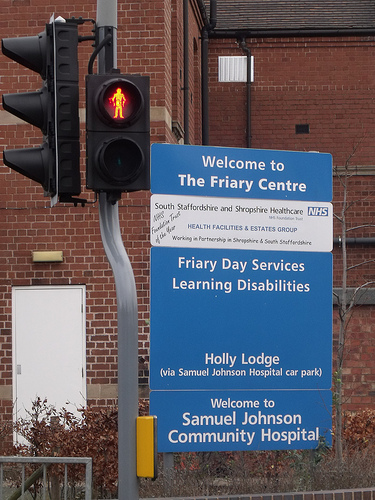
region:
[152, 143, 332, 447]
The sign is blue and white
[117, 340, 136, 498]
The pole is gray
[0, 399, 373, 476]
The bushes are brown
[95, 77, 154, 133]
It is ok to walk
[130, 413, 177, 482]
The box is yellow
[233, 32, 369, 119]
The building is brick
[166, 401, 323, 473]
This is Samuel Johnson Community Hospital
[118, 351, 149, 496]
The pole is metal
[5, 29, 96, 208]
There are 3 traffic lights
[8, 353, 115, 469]
The door is white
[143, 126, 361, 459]
sign is blue and white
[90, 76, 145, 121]
person is on street light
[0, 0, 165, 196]
the streetlights are black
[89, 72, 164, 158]
the person is orange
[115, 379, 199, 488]
the street object is yellow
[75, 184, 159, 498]
the metal pole is silver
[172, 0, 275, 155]
the pipes are black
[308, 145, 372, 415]
the tree has no leaves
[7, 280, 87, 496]
the door is white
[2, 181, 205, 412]
building is made of brick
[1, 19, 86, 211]
A traffic light.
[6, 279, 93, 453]
A door for the building.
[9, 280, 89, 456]
The door is white.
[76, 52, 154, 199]
A crosswalk light.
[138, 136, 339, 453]
A sign.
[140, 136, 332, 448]
The sign is blue and white.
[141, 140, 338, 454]
The sign is in English.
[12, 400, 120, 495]
The plants are brown.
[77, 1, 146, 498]
A light pole.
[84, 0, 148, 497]
The pole is made of metal.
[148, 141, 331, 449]
an information sign on the sidewalk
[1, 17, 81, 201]
a traffic light on a pole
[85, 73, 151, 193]
a cross walk light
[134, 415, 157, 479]
the crosswalk button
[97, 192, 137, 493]
the traffic light pole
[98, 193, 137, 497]
the cross walk pole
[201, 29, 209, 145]
the metal rain gutter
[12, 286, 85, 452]
a white door on a brick building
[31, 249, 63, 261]
a light above the door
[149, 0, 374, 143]
a red brick building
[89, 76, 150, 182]
black traffic signal on pole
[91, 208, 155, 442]
gray pole on traffic signal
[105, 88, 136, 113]
yellow symbol on traffic light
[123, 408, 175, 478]
yellow box on gray post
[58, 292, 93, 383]
hinges on white door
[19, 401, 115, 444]
red bushes at back of building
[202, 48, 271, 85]
white vent on the wall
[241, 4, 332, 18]
gray tiles on the roof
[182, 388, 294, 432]
white words on blue sign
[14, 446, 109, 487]
portion of gray steps